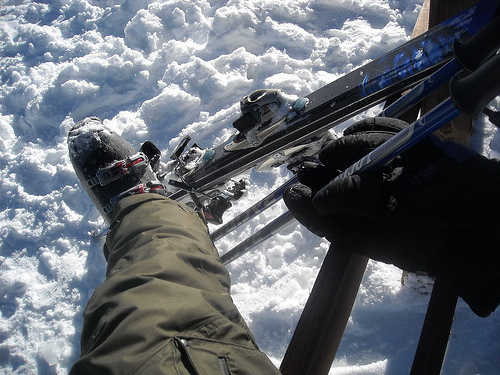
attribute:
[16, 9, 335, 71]
snow — white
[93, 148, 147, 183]
latch — red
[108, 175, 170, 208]
latch — red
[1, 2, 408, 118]
snow — white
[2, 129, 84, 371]
snow — white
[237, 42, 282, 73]
snow — white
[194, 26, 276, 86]
snow — white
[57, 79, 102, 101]
snow — white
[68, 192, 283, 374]
pants — puffy, olive-colored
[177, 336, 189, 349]
button — silver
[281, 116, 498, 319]
black gloves — large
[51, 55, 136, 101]
snow clump — white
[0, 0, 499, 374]
snow — white